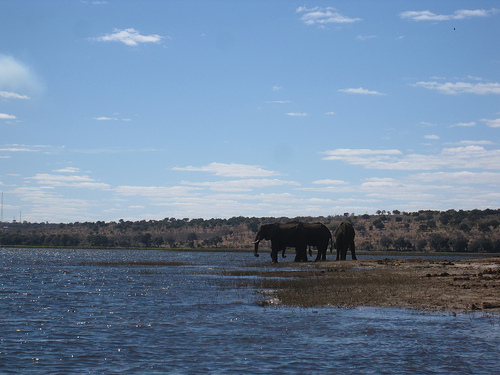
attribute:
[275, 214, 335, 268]
elephant — large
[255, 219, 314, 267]
elephant — large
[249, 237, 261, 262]
trunk — long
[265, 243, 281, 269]
legs — long, thick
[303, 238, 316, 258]
tail — small, gray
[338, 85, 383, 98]
cloud — white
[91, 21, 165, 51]
cloud — white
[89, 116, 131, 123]
cloud — white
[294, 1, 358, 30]
cloud — white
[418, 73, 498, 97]
cloud — white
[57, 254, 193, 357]
water — light hitting